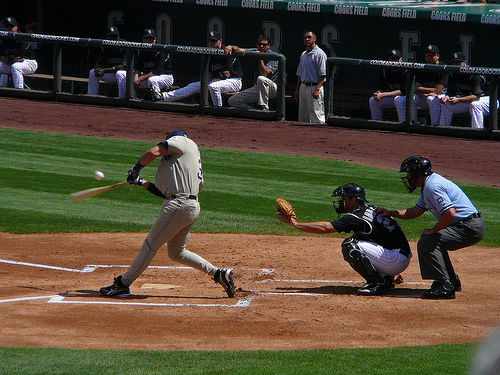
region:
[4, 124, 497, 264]
The grass is green.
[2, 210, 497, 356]
The dirt is brown.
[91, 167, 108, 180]
The ball is white.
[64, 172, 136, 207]
The baseball bat is brown.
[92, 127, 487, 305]
Three people playing baseball.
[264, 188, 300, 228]
Catcher as mitt on.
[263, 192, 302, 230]
the mitt is brown.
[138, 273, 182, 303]
Home plate is dirty.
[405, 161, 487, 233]
Umpire's shirt is blue.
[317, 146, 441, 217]
The helmets are black.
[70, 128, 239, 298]
man hitting a ball with a bat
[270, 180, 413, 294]
catcher with his arm extended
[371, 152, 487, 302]
umpire standing behind the catcher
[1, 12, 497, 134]
people sitting at the edge of the field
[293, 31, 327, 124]
man standing up in a gray polo shirt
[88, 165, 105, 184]
a baseball in midair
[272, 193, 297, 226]
a baseball glove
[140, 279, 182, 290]
home plate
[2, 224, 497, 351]
a patch of clay on the ground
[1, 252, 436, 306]
white lines painted on the field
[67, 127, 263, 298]
Batter getting ready to hit ball.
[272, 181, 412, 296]
Catcher waiting to catch the baseball.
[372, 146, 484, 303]
Umpire waiting to call a play.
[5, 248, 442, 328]
White lines marking off home plate.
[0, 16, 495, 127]
Numerous players watching the baseball game.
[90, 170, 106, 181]
Baseball in mid-air.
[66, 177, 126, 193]
Bat being swung to hit the ball.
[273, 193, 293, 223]
Catcher's mitt reaching out to catch ball.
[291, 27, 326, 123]
Man not in uniform watching game.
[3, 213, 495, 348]
Red dirt on home plate.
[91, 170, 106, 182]
White baseball in the air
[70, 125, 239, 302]
Baseball player swinging a bat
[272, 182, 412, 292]
Catcher behind home plate.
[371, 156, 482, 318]
Umpire watching the play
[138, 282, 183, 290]
Base is covered with dirt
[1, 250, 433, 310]
White lines painted in dirt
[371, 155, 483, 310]
Umpire wearing light blue shirt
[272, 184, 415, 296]
Catcher wearing baseball glove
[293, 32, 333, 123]
Man wearing a blue shirt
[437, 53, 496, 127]
A player wearing white pants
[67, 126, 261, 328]
man swing bat at baseball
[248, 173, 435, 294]
catcher holding glove up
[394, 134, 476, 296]
umpire in black helmet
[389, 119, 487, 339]
umpire in blue shirt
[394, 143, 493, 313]
umpire in grey pants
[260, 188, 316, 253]
brown baseball glove in photo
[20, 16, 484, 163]
team members on the sideline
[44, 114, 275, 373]
batter at home plate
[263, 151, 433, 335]
catcher in ready position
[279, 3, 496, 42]
green banner with white lettering